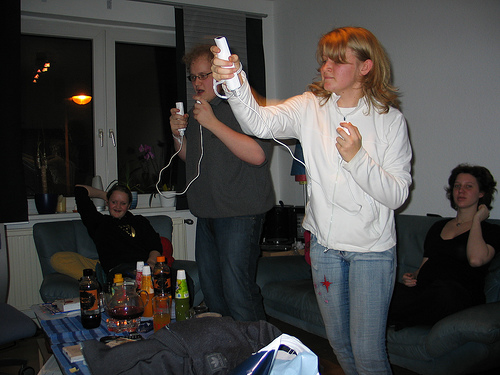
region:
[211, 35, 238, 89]
a Wii game controller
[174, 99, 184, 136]
a Wii game controller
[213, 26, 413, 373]
a girl playing a video game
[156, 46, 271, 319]
a person playing a video game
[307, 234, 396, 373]
a pair of faded jeans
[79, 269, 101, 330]
a clear plastic bottle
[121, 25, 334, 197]
Two wii remotes in the people's hand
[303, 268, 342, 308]
Designs on the girl's jeans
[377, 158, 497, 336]
Woman sitting on a couch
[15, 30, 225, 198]
Photo taken during the night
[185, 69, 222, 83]
Glasses on the person's face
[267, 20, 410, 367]
Girl wearing a white coat and jeans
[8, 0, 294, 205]
The blinds are open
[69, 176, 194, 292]
Girl sitting on a chair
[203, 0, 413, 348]
Blond girl with her right arm up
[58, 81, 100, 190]
Street lamp seen outside the window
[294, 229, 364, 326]
Painted red star on blue jeans.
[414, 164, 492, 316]
Woman couch staring photographer.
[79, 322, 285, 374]
Black backpack in front players.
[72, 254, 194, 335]
Various liquid refreshments table.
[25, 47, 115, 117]
Room lights reflected dark window.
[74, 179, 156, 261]
Girl chair right arm behind head.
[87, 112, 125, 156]
White handles window open/close.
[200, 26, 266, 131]
Wii remote prevalent right hand.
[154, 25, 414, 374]
two people holding wii motes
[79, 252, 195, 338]
alcohol bottles on table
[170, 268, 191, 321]
green bottle on table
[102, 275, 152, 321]
glass pitcher on table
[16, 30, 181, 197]
glass window behind people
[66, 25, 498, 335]
four people shown in picture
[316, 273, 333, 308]
red stars on jeans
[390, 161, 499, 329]
woman in black is pregnant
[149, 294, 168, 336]
orange glass on table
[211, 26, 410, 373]
blonde woman wearing white shirt and blue jeans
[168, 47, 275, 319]
a boy playing a video game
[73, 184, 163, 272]
a girl sitting on a blue chair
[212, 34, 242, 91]
white Nintendo Wii controller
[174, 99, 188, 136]
white Nintendo Wii controller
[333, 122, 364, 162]
a blonde girl's left hand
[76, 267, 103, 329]
a plastic drink bottle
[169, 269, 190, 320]
a green bottle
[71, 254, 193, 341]
drinks clutter coffee table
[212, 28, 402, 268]
woman in white jacket playing with Wii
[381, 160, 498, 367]
woman wearing all black sitting on couch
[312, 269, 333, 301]
red spots on blue jeans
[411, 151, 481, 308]
A person is sitting down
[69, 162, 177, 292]
A person is sitting down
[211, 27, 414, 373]
a woman playing a video game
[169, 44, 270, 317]
an older woman playing a video game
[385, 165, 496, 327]
a woman sitting on a couch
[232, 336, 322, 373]
an open plastic bag on a table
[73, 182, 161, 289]
a woman sitting on a chair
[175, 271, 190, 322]
a glass of green fluid on a table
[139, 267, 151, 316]
a bottle of orange fluid on a table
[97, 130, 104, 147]
a handle on a window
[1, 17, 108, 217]
a window in a room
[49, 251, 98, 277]
a tan pillow on a chair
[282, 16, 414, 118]
head of the girl